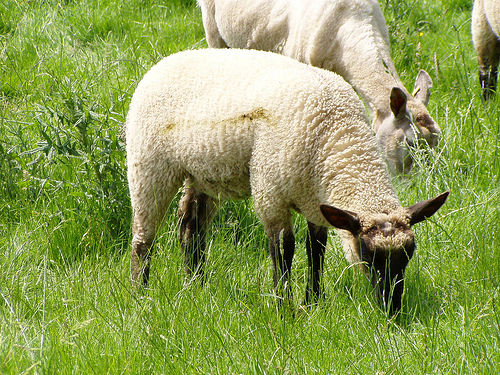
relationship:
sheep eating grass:
[129, 46, 450, 317] [1, 1, 499, 370]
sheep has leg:
[129, 46, 450, 317] [125, 155, 188, 295]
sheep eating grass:
[200, 2, 443, 180] [1, 1, 499, 370]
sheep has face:
[129, 46, 450, 317] [354, 230, 417, 321]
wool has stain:
[125, 48, 415, 264] [162, 105, 272, 132]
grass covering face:
[1, 1, 499, 370] [354, 230, 417, 321]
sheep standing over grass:
[129, 46, 450, 317] [1, 1, 499, 370]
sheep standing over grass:
[200, 2, 443, 180] [1, 1, 499, 370]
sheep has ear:
[129, 46, 450, 317] [319, 205, 358, 233]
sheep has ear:
[129, 46, 450, 317] [407, 190, 449, 226]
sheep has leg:
[129, 46, 450, 317] [305, 220, 328, 308]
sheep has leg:
[129, 46, 450, 317] [179, 193, 205, 286]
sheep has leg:
[129, 46, 450, 317] [269, 230, 296, 321]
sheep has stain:
[129, 46, 450, 317] [162, 105, 272, 132]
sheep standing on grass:
[129, 46, 450, 317] [1, 1, 499, 370]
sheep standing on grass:
[200, 2, 443, 180] [1, 1, 499, 370]